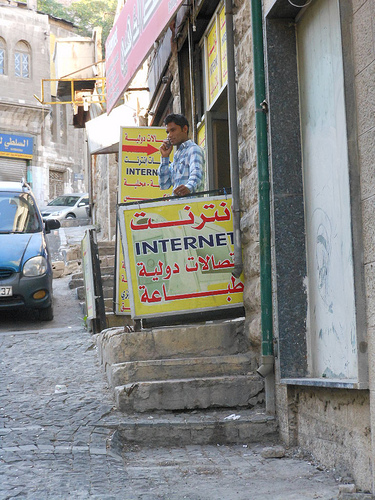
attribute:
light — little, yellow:
[30, 288, 47, 299]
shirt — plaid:
[155, 133, 205, 195]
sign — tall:
[117, 188, 256, 319]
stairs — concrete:
[107, 314, 303, 458]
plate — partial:
[1, 285, 12, 297]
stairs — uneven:
[83, 225, 132, 327]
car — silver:
[44, 195, 91, 216]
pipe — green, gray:
[228, 23, 311, 106]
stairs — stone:
[96, 315, 282, 450]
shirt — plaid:
[142, 143, 207, 201]